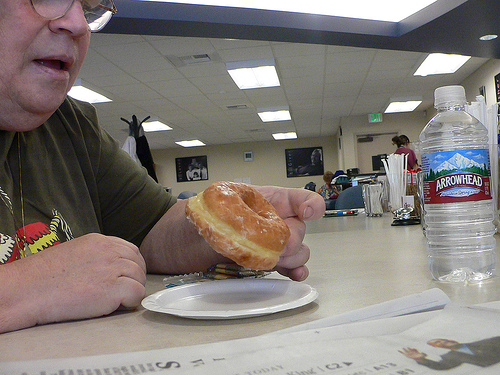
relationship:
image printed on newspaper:
[397, 334, 498, 372] [1, 289, 496, 371]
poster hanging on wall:
[280, 141, 328, 180] [128, 134, 339, 192]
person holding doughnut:
[0, 0, 326, 333] [181, 178, 293, 272]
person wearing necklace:
[0, 0, 326, 333] [2, 134, 33, 257]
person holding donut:
[21, 20, 136, 282] [192, 181, 296, 268]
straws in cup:
[368, 145, 420, 215] [378, 161, 415, 222]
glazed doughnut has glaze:
[184, 181, 292, 270] [217, 187, 274, 242]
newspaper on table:
[7, 300, 487, 374] [0, 180, 498, 371]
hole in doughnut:
[238, 190, 270, 222] [183, 177, 290, 267]